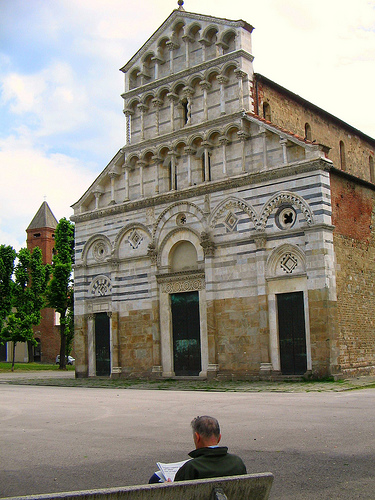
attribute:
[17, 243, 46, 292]
leaves — green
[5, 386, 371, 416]
pavement — gray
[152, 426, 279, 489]
man — reading, sitting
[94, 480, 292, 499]
bench — gray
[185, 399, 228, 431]
hair — grey, gray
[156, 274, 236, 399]
door — green, here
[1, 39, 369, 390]
building — white, brick, large, old, tan, here, striped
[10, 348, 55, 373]
grass — here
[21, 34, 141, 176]
sky — blue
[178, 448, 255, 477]
jacket — green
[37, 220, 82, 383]
tree — green, here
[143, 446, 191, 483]
paper — read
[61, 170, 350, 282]
window — arched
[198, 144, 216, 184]
pillar — small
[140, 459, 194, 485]
newspaper — read, here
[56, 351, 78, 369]
car — here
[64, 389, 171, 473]
road — grey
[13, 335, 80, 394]
yard — green